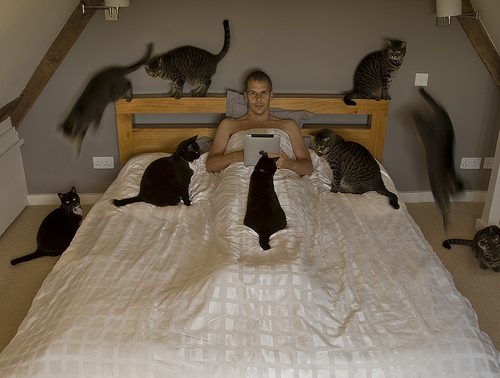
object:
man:
[205, 70, 313, 179]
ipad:
[244, 131, 283, 168]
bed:
[0, 91, 499, 375]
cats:
[312, 126, 403, 211]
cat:
[109, 134, 203, 216]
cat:
[53, 32, 154, 156]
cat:
[9, 186, 83, 267]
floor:
[3, 274, 24, 305]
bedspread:
[3, 149, 498, 377]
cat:
[240, 153, 290, 253]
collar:
[255, 168, 274, 175]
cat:
[413, 83, 471, 232]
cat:
[342, 35, 410, 106]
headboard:
[114, 95, 391, 167]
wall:
[17, 0, 499, 191]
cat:
[146, 18, 233, 99]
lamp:
[434, 0, 481, 27]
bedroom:
[5, 3, 496, 377]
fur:
[243, 152, 288, 249]